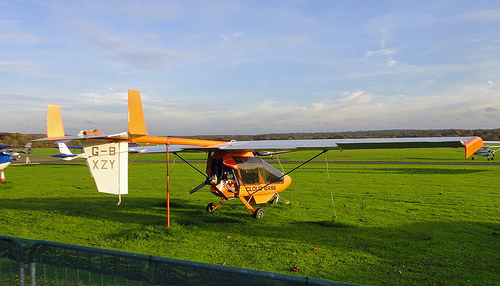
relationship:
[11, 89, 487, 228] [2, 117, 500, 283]
helicopter on field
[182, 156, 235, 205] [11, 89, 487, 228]
motor front of helicopter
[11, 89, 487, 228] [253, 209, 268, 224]
helicopter has wheel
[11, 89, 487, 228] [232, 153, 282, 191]
helicopter has cockpit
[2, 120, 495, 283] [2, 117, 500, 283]
field with field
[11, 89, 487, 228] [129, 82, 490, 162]
helicopter has wing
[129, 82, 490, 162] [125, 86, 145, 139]
wing has end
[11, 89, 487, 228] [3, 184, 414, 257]
helicopter has shadow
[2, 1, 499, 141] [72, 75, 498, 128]
sky with cloud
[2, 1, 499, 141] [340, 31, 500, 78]
sky with cloud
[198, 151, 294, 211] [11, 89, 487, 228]
cabin on helicopter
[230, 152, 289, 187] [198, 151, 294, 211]
window on cabin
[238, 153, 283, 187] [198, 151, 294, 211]
window on cabin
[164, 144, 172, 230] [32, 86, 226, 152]
pole for tail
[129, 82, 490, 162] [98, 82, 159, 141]
wing has tail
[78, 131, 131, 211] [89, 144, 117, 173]
tagging reads g-b xyz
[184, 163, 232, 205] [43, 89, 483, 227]
motor on helicopter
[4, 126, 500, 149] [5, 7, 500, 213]
ranges in background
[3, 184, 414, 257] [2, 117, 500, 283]
shadow on field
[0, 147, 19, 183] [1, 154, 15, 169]
plane has nose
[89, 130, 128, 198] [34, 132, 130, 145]
identification on flap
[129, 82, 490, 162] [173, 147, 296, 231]
wing over body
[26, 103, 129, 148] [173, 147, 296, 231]
wing over body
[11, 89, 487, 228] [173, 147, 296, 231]
helicopter has body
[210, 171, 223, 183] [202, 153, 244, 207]
panel on back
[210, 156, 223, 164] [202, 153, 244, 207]
panel on back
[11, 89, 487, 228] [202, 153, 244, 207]
helicopter has back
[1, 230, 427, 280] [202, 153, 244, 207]
fencing near back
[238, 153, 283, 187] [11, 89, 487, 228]
window on helicopter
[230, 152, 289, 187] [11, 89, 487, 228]
window on helicopter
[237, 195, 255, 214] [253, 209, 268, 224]
support for wheel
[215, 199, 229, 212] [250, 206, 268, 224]
support for wheel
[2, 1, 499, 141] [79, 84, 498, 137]
sky with line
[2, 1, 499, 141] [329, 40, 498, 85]
sky with line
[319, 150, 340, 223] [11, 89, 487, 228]
wire attaching helicopter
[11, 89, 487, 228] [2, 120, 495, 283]
helicopter attached to ground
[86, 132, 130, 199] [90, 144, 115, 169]
wing with letters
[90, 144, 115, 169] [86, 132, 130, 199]
letters on wing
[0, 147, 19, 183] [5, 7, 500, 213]
plane in distance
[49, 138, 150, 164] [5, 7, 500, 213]
plane in distance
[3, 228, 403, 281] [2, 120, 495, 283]
railing next to field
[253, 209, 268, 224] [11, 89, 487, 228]
wheel on helicopter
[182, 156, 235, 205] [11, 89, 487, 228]
motor on helicopter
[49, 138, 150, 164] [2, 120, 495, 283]
plane on field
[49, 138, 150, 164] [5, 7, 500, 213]
plane in background